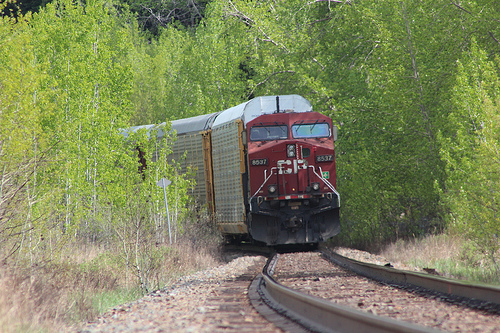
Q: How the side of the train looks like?
A: Grassy.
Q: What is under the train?
A: Track.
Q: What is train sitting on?
A: Track.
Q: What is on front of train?
A: Windshield.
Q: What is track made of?
A: Metal.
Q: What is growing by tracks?
A: Trees.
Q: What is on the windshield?
A: Wipers.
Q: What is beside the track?
A: Gravel.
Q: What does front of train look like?
A: Red.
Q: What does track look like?
A: Rusty.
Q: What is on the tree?
A: Leaves.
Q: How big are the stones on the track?
A: Tiny.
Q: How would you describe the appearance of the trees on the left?
A: Light green.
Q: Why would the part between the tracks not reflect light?
A: It is black.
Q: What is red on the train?
A: The front.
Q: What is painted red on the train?
A: The front.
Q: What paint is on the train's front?
A: Red.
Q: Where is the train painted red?
A: The front.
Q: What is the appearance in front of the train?
A: Red.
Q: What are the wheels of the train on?
A: On the tracks.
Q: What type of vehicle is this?
A: A train.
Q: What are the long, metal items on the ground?
A: Train tracks.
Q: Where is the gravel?
A: Between and around the train tracks.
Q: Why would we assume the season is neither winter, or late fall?
A: The trees are leafy and green.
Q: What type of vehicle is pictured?
A: Train.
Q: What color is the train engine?
A: Red.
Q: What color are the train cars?
A: Silver.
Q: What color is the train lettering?
A: White.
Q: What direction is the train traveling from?
A: Left.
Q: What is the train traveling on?
A: Rails.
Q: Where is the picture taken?
A: On a railroad.